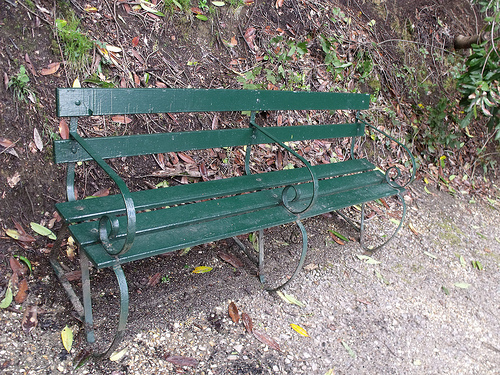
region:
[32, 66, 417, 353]
Green bench on side of street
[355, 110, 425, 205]
Right armrest of bench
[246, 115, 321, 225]
Armrest in center of bench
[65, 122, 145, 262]
Armrest on left of bench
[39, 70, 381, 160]
Backrest of bench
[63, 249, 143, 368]
Left leg of bench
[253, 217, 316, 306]
Leg of bench in center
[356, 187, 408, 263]
Right leg bench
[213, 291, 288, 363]
Dry leaves on floor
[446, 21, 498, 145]
Green branch on left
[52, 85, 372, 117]
a green wooden plank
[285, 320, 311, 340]
a yellow leaf on the ground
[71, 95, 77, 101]
a green metal bolt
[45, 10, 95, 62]
a patch of green grass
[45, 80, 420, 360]
a green wood and metal park bench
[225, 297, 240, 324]
a brown leaf on the ground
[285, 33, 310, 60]
green tree leaves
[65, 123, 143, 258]
a green metal armrest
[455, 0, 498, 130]
low hanging tree branches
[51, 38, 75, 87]
a brown twig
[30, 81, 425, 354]
Green bench outdoor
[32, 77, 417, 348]
Green metal bench outdoor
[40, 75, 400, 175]
Back of metal green bench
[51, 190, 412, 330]
Curved support of bench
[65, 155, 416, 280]
Seat of metal bench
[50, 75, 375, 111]
Top rail of beanch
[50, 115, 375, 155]
Low rail of beanch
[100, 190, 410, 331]
Front support of beanch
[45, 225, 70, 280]
Rear support of beach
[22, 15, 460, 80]
Dry leaves behind bench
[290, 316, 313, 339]
A small bright yellow leaf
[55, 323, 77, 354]
A small soft yellow leaf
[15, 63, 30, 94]
A small green plant growing in dirt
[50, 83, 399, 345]
A dark green bench near the side of a hill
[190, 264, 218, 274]
A small yellow and green leaf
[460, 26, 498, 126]
A leafy green tree branch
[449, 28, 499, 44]
A tree trunk in the side of a hill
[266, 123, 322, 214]
A curled metal armrest on a bench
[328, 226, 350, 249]
A brown leaf and a green leaf together on the ground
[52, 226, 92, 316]
Rusted metal base on a green bench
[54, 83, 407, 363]
a green park bench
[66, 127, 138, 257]
filigree armrest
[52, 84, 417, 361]
the park bench has filigree arm rests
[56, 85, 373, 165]
the backrest of the bench is made of wooden slats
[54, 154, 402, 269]
the seat of the bench is made of wooden slats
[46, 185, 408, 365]
the bench has filigree legs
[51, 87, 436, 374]
the green park bench sits on a gravel path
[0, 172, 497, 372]
a gravel path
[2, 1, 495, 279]
there is a hill behind the park bench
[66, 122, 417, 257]
the filigree arms are green